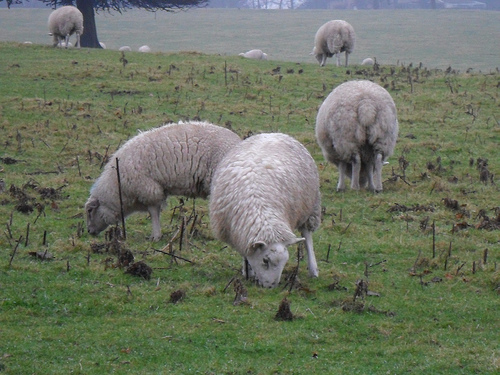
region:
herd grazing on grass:
[32, 18, 445, 324]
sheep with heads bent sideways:
[200, 155, 350, 310]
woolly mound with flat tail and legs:
[310, 60, 430, 200]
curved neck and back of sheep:
[65, 111, 241, 236]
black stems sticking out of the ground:
[60, 90, 465, 330]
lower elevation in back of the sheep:
[65, 25, 467, 285]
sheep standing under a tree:
[25, 4, 117, 50]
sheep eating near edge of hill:
[295, 10, 365, 70]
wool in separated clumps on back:
[216, 135, 296, 222]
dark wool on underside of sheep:
[165, 160, 210, 215]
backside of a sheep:
[315, 76, 405, 194]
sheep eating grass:
[220, 129, 325, 287]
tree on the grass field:
[6, 1, 207, 54]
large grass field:
[3, 42, 497, 372]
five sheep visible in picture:
[1, 3, 496, 373]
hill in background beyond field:
[3, 8, 495, 65]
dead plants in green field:
[16, 219, 196, 279]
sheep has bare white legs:
[302, 224, 325, 279]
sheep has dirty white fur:
[78, 115, 325, 285]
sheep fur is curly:
[83, 119, 239, 238]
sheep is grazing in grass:
[193, 112, 343, 304]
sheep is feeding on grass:
[296, 63, 412, 212]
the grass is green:
[0, 33, 498, 370]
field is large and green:
[0, 6, 498, 369]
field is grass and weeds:
[1, 5, 496, 371]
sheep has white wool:
[34, 6, 96, 51]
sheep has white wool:
[303, 8, 366, 78]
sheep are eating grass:
[72, 93, 344, 315]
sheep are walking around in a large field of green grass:
[41, 3, 448, 338]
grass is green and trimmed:
[1, 6, 498, 371]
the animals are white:
[40, 10, 450, 320]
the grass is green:
[365, 290, 415, 345]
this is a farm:
[10, 35, 475, 365]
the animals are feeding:
[80, 86, 460, 342]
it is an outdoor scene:
[16, 15, 448, 330]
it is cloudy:
[6, 60, 491, 366]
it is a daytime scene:
[10, 67, 465, 332]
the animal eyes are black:
[175, 187, 372, 313]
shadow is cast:
[340, 170, 390, 201]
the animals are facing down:
[36, 86, 481, 336]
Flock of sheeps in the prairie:
[32, 0, 413, 302]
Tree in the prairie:
[15, 0, 205, 50]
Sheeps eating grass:
[36, 5, 421, 311]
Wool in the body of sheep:
[205, 125, 332, 246]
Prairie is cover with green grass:
[3, 46, 498, 373]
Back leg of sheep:
[303, 224, 332, 289]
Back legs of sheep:
[351, 149, 390, 202]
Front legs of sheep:
[144, 191, 176, 248]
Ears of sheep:
[247, 233, 310, 253]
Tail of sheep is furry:
[352, 89, 381, 130]